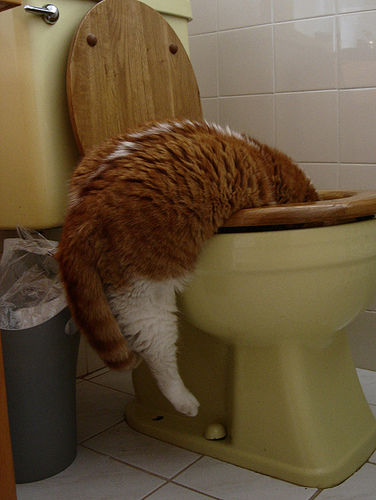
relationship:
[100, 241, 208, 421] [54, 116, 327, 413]
leg of cat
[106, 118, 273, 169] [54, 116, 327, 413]
back of cat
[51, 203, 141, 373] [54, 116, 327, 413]
tail of cat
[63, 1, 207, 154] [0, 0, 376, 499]
lid of bathroom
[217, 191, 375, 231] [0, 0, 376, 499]
seat of bathroom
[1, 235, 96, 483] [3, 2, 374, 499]
trash can of bathroom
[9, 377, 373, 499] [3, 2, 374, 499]
floor of bathroom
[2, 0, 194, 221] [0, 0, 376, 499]
tank of bathroom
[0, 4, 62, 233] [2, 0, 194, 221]
side of tank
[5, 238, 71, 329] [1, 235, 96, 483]
bag in trash can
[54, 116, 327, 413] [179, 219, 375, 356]
cat in bowl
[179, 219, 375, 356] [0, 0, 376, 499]
bowl of bathroom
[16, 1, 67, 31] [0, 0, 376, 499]
handle of bathroom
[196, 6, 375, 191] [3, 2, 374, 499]
wall in bathroom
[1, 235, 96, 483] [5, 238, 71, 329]
trash can with bag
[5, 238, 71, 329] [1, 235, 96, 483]
bag in can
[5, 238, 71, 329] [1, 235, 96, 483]
bag for can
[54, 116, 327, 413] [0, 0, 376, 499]
cat in bathroom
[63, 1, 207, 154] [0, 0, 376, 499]
seat cover for bathroom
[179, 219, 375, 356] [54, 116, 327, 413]
bowl with cat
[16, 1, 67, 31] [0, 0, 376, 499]
flusher of bathroom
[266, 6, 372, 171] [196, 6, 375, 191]
tiles on wall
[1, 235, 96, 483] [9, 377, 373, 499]
bin on floor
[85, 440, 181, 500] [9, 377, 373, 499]
tiles on floor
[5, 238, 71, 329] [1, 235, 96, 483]
bag in trash bin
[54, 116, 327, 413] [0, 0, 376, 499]
cat climbing in bathroom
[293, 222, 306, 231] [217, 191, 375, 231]
stopper on seat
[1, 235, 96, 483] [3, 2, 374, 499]
garbage can in bathroom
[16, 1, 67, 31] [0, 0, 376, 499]
handle on bathroom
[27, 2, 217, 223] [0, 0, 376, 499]
back of bathroom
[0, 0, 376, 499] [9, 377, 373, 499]
bathroom sitting on floor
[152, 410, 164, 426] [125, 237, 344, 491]
spot on side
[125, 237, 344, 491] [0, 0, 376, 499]
side of bathroom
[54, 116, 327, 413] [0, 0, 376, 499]
cat inside bathroom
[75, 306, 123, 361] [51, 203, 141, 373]
stripes on tail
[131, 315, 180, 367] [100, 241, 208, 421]
fur on leg